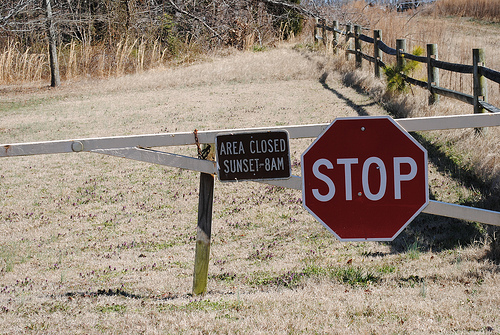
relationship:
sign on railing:
[212, 132, 297, 186] [5, 109, 499, 290]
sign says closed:
[212, 132, 297, 186] [247, 135, 288, 155]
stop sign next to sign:
[299, 112, 434, 242] [212, 132, 297, 186]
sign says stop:
[299, 112, 434, 242] [313, 156, 419, 205]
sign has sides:
[299, 112, 434, 242] [420, 145, 436, 208]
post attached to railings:
[192, 138, 216, 300] [5, 109, 499, 290]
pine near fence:
[1, 1, 109, 86] [312, 17, 499, 115]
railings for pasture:
[5, 109, 499, 290] [358, 3, 498, 70]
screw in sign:
[244, 133, 256, 142] [212, 132, 297, 186]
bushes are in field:
[429, 3, 497, 21] [358, 3, 498, 70]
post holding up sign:
[192, 138, 216, 300] [212, 132, 297, 186]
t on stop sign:
[335, 155, 363, 203] [299, 112, 434, 242]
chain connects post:
[188, 126, 215, 164] [192, 138, 216, 300]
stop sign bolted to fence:
[299, 112, 434, 242] [5, 109, 499, 290]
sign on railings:
[212, 132, 297, 186] [5, 109, 499, 290]